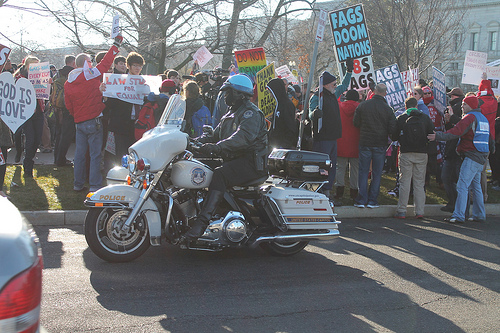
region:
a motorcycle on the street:
[62, 75, 362, 274]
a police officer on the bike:
[120, 57, 329, 263]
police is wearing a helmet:
[195, 57, 262, 109]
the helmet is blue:
[199, 50, 258, 99]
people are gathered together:
[0, 20, 475, 209]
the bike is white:
[90, 103, 356, 259]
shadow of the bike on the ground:
[60, 238, 440, 318]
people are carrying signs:
[116, 7, 476, 141]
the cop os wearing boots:
[163, 164, 253, 236]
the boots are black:
[153, 155, 262, 255]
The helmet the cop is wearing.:
[222, 76, 259, 91]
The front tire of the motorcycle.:
[91, 209, 145, 257]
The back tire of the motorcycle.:
[262, 230, 312, 255]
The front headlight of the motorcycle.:
[130, 152, 137, 169]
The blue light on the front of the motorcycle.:
[120, 154, 128, 164]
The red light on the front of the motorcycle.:
[137, 161, 143, 167]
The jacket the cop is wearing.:
[216, 108, 265, 148]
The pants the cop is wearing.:
[207, 148, 260, 186]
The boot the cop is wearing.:
[192, 188, 218, 238]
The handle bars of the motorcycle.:
[181, 126, 215, 158]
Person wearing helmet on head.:
[212, 65, 267, 120]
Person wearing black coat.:
[206, 113, 283, 166]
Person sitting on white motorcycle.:
[118, 134, 284, 234]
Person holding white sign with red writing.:
[102, 72, 168, 134]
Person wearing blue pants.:
[447, 169, 496, 215]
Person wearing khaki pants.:
[393, 153, 457, 220]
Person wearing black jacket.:
[353, 100, 394, 131]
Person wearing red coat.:
[336, 95, 373, 178]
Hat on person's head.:
[313, 64, 335, 76]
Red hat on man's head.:
[461, 90, 479, 123]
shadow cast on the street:
[323, 265, 455, 302]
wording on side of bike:
[91, 193, 138, 209]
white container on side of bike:
[259, 185, 344, 246]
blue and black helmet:
[208, 68, 281, 103]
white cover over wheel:
[79, 183, 195, 250]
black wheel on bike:
[84, 199, 169, 266]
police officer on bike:
[131, 81, 329, 239]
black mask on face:
[212, 80, 271, 109]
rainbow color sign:
[213, 41, 290, 74]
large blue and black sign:
[310, 1, 394, 93]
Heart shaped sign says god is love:
[0, 68, 45, 133]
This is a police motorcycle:
[81, 110, 338, 260]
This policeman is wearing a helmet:
[212, 68, 258, 107]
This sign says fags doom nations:
[326, 6, 372, 60]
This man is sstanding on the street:
[392, 92, 432, 222]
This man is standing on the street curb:
[352, 83, 395, 209]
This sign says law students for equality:
[102, 70, 166, 103]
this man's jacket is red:
[65, 51, 107, 129]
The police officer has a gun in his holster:
[248, 146, 272, 173]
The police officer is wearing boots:
[195, 183, 231, 244]